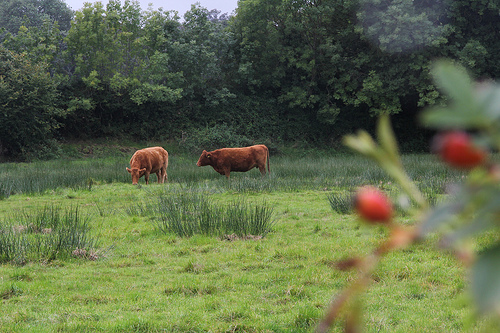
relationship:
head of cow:
[123, 159, 148, 185] [122, 142, 172, 188]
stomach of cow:
[232, 157, 255, 174] [193, 135, 272, 179]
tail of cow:
[262, 145, 272, 169] [193, 135, 272, 179]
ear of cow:
[123, 163, 135, 172] [193, 135, 272, 179]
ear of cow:
[136, 164, 149, 174] [122, 142, 175, 185]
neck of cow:
[206, 149, 219, 167] [193, 135, 272, 179]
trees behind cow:
[69, 9, 282, 145] [121, 143, 171, 185]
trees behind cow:
[69, 9, 282, 145] [193, 139, 273, 184]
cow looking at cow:
[193, 135, 272, 179] [122, 140, 174, 190]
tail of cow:
[262, 146, 270, 173] [193, 135, 272, 179]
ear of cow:
[140, 166, 150, 175] [122, 142, 175, 185]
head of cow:
[191, 146, 213, 169] [193, 135, 272, 179]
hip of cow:
[252, 149, 266, 166] [193, 135, 272, 179]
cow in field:
[193, 135, 272, 179] [4, 151, 477, 330]